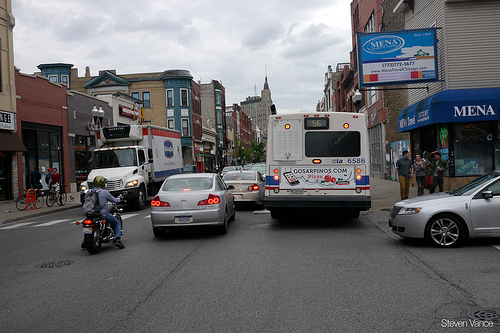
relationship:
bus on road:
[260, 111, 372, 220] [0, 176, 500, 333]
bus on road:
[260, 111, 372, 220] [6, 200, 482, 326]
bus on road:
[260, 111, 372, 220] [88, 199, 440, 331]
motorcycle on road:
[76, 188, 131, 251] [6, 200, 482, 326]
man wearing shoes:
[77, 175, 134, 258] [79, 225, 129, 255]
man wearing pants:
[80, 175, 127, 249] [104, 209, 123, 242]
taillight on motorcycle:
[84, 221, 94, 229] [72, 193, 126, 254]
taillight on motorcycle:
[80, 218, 94, 226] [78, 189, 130, 254]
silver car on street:
[150, 173, 236, 239] [2, 194, 497, 326]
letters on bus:
[276, 157, 366, 197] [256, 80, 375, 258]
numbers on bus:
[346, 155, 366, 165] [260, 111, 372, 220]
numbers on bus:
[304, 113, 329, 134] [303, 105, 382, 219]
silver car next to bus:
[150, 173, 236, 239] [260, 111, 372, 220]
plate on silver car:
[169, 215, 195, 232] [150, 173, 236, 239]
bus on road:
[246, 97, 416, 228] [3, 167, 497, 331]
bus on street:
[260, 111, 372, 220] [2, 194, 497, 326]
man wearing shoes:
[80, 175, 127, 249] [112, 234, 127, 254]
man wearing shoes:
[80, 175, 127, 249] [112, 236, 127, 249]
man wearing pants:
[80, 175, 127, 249] [427, 176, 444, 192]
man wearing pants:
[80, 175, 127, 249] [397, 175, 410, 199]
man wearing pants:
[80, 175, 127, 249] [103, 215, 120, 236]